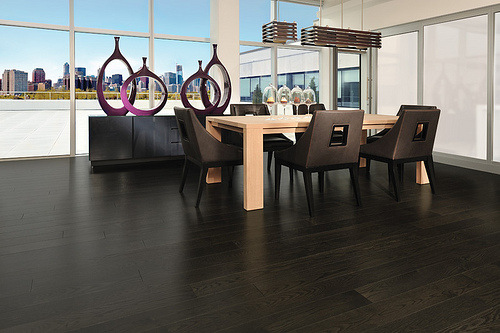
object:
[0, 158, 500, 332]
floor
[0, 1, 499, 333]
room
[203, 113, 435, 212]
table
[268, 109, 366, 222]
chair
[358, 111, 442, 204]
chair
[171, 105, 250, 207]
chair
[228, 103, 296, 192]
chair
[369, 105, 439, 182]
chair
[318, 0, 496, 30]
wall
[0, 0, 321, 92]
sky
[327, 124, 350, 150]
hole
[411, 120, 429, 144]
hole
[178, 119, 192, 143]
hole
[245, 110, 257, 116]
hole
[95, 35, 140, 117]
vase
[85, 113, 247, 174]
table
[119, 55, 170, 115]
vase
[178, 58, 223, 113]
vase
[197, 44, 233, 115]
vase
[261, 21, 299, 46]
light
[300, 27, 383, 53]
light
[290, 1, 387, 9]
ceiling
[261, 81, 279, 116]
decoration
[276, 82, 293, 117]
decoration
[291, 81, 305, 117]
decoration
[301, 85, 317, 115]
decoration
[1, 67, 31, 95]
building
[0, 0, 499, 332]
background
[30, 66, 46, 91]
building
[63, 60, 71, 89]
building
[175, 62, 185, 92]
building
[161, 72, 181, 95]
building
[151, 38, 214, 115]
window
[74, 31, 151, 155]
window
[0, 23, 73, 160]
window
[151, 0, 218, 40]
window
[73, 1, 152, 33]
window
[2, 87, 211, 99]
railing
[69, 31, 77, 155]
post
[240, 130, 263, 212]
leg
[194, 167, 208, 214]
leg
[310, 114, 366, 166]
back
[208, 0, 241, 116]
pillar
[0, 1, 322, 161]
wall